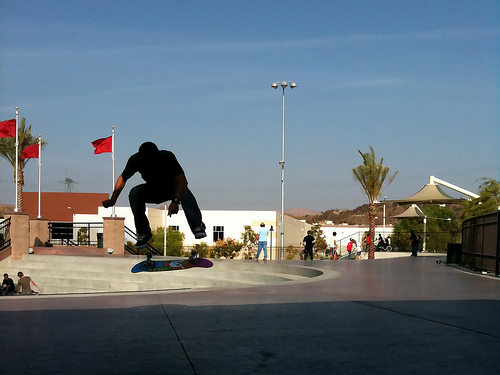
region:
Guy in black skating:
[97, 139, 209, 246]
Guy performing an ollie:
[99, 140, 216, 282]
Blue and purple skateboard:
[126, 246, 217, 277]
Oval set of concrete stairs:
[0, 254, 335, 304]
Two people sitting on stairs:
[3, 271, 40, 295]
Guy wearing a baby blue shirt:
[253, 222, 271, 261]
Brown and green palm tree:
[351, 147, 398, 259]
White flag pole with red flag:
[91, 126, 126, 213]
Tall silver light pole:
[265, 78, 302, 256]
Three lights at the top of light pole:
[263, 75, 299, 99]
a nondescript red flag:
[0, 108, 22, 213]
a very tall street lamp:
[270, 82, 300, 257]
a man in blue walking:
[255, 223, 270, 261]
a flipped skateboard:
[130, 250, 219, 272]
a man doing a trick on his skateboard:
[98, 142, 215, 274]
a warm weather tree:
[349, 147, 395, 259]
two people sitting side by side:
[1, 268, 39, 300]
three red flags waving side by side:
[0, 105, 120, 220]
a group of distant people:
[248, 220, 375, 265]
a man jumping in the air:
[100, 140, 215, 250]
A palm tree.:
[353, 145, 393, 263]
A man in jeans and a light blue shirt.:
[250, 220, 272, 264]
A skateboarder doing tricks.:
[100, 131, 215, 279]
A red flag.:
[19, 133, 46, 215]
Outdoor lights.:
[268, 76, 299, 261]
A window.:
[211, 221, 225, 238]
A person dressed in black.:
[301, 228, 316, 263]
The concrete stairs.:
[45, 254, 98, 289]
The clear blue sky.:
[193, 117, 245, 172]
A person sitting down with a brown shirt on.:
[15, 271, 37, 300]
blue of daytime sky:
[3, 2, 498, 204]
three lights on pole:
[269, 79, 295, 257]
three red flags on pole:
[2, 107, 114, 216]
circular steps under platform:
[40, 257, 320, 295]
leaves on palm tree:
[355, 146, 390, 259]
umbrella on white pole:
[400, 174, 477, 206]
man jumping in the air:
[104, 140, 206, 250]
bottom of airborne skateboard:
[131, 251, 216, 273]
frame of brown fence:
[459, 213, 496, 273]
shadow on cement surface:
[0, 295, 497, 371]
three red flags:
[0, 107, 115, 212]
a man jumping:
[91, 142, 212, 273]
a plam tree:
[355, 152, 383, 262]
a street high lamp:
[271, 81, 293, 261]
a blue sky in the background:
[13, 46, 257, 80]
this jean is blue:
[255, 241, 270, 260]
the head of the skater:
[139, 142, 156, 161]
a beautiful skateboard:
[126, 253, 211, 273]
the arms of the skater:
[101, 158, 190, 215]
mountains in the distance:
[321, 204, 404, 224]